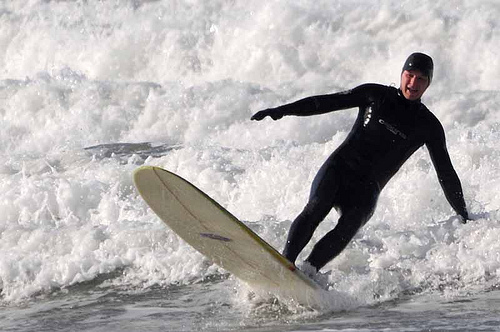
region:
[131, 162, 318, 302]
a white surfboard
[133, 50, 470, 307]
a man on a surfboard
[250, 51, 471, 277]
a man in water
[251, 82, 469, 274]
a man's black wetsuit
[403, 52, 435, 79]
a black wetsuit cap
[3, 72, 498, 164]
a white crashing wave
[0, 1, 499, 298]
white foams in the ocean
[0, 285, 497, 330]
calm section of the water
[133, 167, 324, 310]
large surfboard in the ocean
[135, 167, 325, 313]
large white surfboard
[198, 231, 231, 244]
logo on the bottom of the surfboard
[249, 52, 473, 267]
man surfing in the ocean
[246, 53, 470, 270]
man wearing a tight wetsuit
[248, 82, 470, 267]
black wet suit for surfing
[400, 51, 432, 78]
black swim cap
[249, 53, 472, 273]
man on a surfboard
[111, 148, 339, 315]
this is a surfboard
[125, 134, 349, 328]
the surfboard is white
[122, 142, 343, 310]
front of board is up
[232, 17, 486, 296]
this is a man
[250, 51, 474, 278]
man wearing a wet suit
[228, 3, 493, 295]
the wet suit is black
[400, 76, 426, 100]
man has mouth open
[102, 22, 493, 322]
man is riding a surfboard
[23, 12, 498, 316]
waves in the water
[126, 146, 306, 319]
a line on the board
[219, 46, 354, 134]
The person has his arm out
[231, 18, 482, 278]
The person is wearing a wet suit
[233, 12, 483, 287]
The person is wearing a black wet suit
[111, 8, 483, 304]
The person is riding a surfboard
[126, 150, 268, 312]
The surfboard is white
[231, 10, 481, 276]
The person is leaning backwards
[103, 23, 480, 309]
The person is surfing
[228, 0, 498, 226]
The person is in the water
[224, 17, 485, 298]
The person is riding the waves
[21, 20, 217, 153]
Waves in the water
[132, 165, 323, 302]
large surfboard in the ocean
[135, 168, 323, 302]
large, white surfboard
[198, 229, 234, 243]
a logo on the bottom of the surface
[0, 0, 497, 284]
white foam in the water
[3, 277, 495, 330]
calm section of water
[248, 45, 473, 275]
man surfing in the ocean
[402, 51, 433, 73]
a black swim cap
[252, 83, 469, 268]
tight black wet suit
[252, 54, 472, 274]
person in a wet suit surfing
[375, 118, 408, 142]
writing on the front of wet suit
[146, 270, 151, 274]
a drop of water in the ocean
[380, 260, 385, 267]
a drop of water in the ocean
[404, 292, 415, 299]
a drop of water in the ocean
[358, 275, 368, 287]
a drop of water in the ocean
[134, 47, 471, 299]
man is on surfboard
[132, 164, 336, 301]
surfboard is in the water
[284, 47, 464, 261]
body suit is black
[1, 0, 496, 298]
wave is behind man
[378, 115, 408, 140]
logo is on body suit